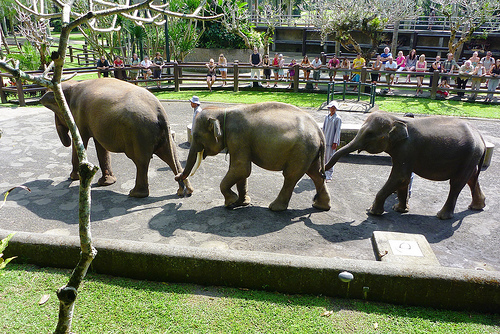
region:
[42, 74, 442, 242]
Elephants walking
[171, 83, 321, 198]
Elephant with tusk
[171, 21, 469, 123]
People watching the show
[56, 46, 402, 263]
People watching the elephants doing a show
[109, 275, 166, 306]
Grass around the enclosure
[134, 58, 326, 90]
People on the fence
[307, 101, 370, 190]
Caretaker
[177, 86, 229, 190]
The trainer with the elephants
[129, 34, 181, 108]
A visitor watching the elephant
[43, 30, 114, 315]
A tree near the enclosure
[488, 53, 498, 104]
Person in dark shirt and light short at the far right of then fence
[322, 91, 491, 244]
Smallest elephant of three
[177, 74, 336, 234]
Medium elephant of three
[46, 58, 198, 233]
largest elephant of three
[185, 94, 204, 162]
1st elephant trainer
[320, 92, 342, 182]
2nd elephant trainer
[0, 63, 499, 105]
wooden fence with lots of people standing beside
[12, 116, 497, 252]
cement platform that the elephants are walking on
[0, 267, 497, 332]
Grassy area in front of the cement platform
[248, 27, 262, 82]
person in black top and light colored shorts standing on fence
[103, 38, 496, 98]
a group of people stand near a fence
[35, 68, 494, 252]
a trio of elephants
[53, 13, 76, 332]
trunk of a tree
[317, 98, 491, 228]
an elephants is holding another elephants tail with its trunk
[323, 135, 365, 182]
an elephants trunk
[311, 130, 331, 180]
an elephants tail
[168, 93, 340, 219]
an elephant is holding another elephants tail with its trunk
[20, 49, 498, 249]
a trio of elephants in an enclosure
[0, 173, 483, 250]
shadows of a trio of elephants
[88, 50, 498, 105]
people at a zoo watching animals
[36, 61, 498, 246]
the elephants are walking together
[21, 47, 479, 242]
the elephants have joined trunk to tail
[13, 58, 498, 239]
they elephants appear to be arranged largest to smallest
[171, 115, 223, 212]
this elephant has long tusks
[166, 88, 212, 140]
the man is in charge of the elephants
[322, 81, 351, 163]
another man is helping too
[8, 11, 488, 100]
a railing is separating the elephants from the crowd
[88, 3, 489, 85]
many people have come out to watch the elephants.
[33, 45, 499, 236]
the elephants appear docile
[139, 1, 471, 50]
a building is in the background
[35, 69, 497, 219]
three elephants in a line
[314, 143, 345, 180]
elephant trunk holding tail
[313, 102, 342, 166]
person in hat watching elephants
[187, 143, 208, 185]
tusk on middle elephant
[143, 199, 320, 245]
shadow of elephant on ground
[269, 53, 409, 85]
audience leaning on fence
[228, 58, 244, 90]
post on wood fence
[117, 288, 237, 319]
short green grass next to arena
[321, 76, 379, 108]
semi circular fence facing audience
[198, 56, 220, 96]
person sitting on bottom rail